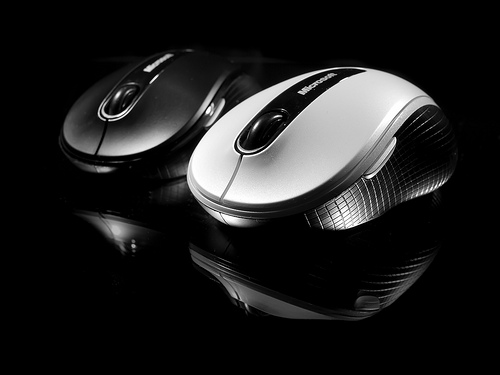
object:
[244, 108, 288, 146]
roller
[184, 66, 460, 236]
mouse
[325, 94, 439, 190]
edge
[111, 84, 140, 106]
part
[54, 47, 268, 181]
mouse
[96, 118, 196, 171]
edge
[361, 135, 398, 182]
tab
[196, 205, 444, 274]
bottom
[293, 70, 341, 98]
logo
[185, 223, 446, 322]
reflection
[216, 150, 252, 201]
line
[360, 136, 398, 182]
button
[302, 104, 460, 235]
curve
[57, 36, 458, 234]
display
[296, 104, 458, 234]
pattern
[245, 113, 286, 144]
wheel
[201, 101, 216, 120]
button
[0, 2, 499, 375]
background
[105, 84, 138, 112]
roller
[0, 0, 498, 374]
desk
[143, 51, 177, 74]
logo